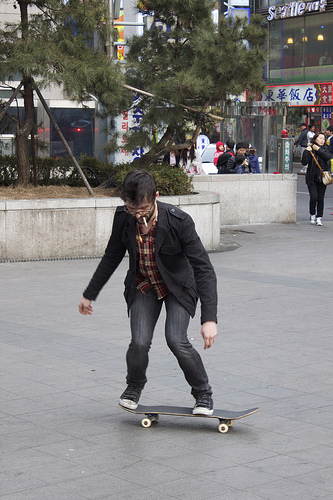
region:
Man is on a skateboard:
[75, 167, 262, 435]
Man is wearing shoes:
[116, 381, 218, 416]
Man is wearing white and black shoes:
[117, 380, 214, 418]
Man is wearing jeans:
[122, 277, 212, 395]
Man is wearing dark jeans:
[123, 279, 211, 396]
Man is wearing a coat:
[80, 201, 218, 326]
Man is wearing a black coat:
[83, 199, 222, 326]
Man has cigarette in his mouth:
[142, 214, 147, 229]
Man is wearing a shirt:
[132, 199, 172, 301]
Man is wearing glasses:
[123, 198, 155, 213]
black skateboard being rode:
[121, 406, 259, 433]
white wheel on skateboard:
[218, 425, 234, 435]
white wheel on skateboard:
[140, 418, 152, 430]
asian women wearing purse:
[302, 132, 331, 226]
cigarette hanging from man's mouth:
[138, 216, 150, 231]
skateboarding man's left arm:
[189, 214, 216, 346]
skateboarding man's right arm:
[79, 204, 125, 319]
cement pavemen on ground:
[0, 438, 136, 495]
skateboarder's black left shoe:
[192, 391, 216, 418]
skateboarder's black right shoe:
[116, 381, 144, 413]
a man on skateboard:
[79, 168, 259, 433]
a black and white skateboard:
[118, 400, 259, 432]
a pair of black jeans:
[126, 287, 209, 392]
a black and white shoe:
[192, 394, 213, 414]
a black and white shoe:
[120, 384, 141, 409]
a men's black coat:
[82, 199, 217, 323]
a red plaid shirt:
[133, 218, 164, 296]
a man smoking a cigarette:
[79, 170, 217, 414]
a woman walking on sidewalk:
[300, 132, 331, 225]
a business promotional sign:
[248, 84, 331, 106]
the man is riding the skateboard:
[129, 177, 236, 436]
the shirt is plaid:
[136, 239, 155, 262]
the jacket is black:
[157, 227, 184, 262]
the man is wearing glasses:
[123, 206, 156, 216]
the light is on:
[284, 31, 296, 48]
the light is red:
[71, 121, 85, 137]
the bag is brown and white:
[317, 165, 332, 189]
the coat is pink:
[212, 138, 223, 161]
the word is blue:
[286, 87, 305, 105]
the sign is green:
[282, 140, 290, 172]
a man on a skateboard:
[24, 143, 328, 463]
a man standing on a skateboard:
[33, 150, 294, 485]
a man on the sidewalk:
[73, 145, 323, 435]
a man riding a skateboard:
[59, 162, 318, 436]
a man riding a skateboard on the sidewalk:
[61, 161, 328, 492]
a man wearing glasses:
[106, 166, 188, 268]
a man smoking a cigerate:
[99, 156, 195, 267]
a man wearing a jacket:
[74, 160, 276, 372]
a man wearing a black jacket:
[52, 154, 242, 356]